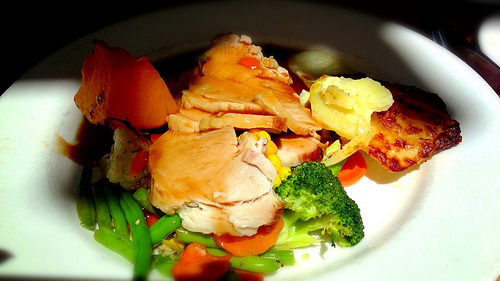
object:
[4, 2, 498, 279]
plate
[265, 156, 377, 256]
broccoli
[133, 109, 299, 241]
turkey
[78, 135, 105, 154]
gravy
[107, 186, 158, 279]
beans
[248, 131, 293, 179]
corn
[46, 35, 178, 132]
carrot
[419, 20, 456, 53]
fork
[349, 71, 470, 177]
potatoes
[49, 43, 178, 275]
vegetables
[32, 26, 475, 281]
food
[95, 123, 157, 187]
cauliflower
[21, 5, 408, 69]
shadow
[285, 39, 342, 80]
squash